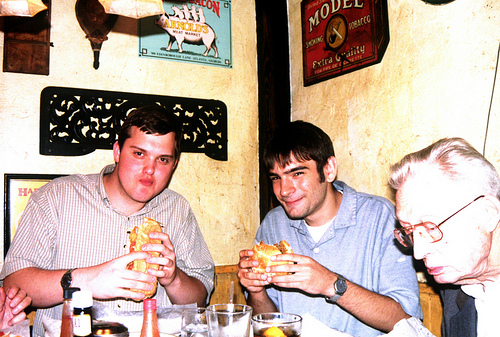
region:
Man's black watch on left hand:
[61, 267, 75, 296]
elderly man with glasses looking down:
[388, 145, 499, 291]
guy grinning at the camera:
[261, 117, 345, 222]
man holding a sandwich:
[237, 238, 331, 295]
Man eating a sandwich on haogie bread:
[121, 214, 168, 298]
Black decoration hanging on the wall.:
[36, 83, 229, 161]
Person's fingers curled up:
[1, 284, 29, 329]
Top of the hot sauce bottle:
[139, 296, 162, 335]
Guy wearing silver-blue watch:
[328, 268, 350, 302]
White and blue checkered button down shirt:
[10, 176, 217, 307]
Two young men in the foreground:
[60, 99, 380, 332]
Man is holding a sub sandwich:
[100, 201, 183, 304]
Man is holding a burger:
[227, 228, 312, 290]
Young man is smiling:
[273, 182, 316, 210]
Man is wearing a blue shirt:
[222, 175, 421, 335]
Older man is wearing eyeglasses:
[379, 188, 481, 264]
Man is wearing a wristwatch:
[49, 261, 85, 304]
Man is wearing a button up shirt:
[11, 158, 218, 314]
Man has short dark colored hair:
[108, 98, 188, 164]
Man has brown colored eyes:
[258, 161, 314, 190]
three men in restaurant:
[87, 109, 491, 326]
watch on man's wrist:
[320, 270, 350, 310]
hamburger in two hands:
[242, 235, 299, 294]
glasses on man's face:
[389, 218, 452, 251]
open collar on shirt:
[95, 198, 169, 220]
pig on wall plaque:
[152, 11, 222, 58]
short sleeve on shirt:
[0, 244, 55, 303]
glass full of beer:
[250, 307, 305, 335]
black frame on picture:
[2, 166, 36, 202]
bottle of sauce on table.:
[75, 297, 92, 332]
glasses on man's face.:
[395, 224, 442, 241]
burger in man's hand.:
[260, 241, 285, 271]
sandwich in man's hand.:
[135, 227, 156, 284]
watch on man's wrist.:
[59, 263, 78, 292]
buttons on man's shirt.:
[121, 225, 128, 250]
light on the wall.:
[95, 6, 152, 21]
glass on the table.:
[218, 305, 245, 331]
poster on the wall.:
[305, 1, 380, 59]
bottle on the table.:
[139, 298, 160, 334]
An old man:
[386, 125, 499, 333]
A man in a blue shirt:
[242, 116, 420, 334]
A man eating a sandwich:
[0, 100, 219, 335]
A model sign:
[300, 0, 393, 83]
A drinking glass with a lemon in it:
[250, 312, 310, 335]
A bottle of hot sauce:
[138, 297, 163, 335]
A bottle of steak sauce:
[68, 287, 98, 333]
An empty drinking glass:
[203, 298, 250, 333]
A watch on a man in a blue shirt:
[323, 265, 346, 308]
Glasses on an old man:
[392, 189, 485, 249]